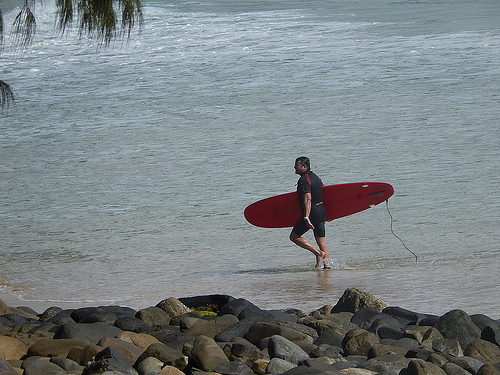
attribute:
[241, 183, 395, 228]
board — red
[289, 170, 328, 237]
wetsuit — black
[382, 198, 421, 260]
cable — black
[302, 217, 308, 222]
watch — white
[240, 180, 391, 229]
board — red, black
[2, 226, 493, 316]
water — shallow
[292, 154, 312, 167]
hair — short, dark, wet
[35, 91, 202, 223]
ocean water — Calm , blue 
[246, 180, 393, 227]
surfboard — dark red, one, red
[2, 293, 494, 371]
rocks — large, dark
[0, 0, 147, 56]
leaves — dripping 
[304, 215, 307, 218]
watch — white 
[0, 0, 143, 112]
tree — green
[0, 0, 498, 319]
water — light grey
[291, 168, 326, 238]
wetsuit — short, black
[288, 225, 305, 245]
knee — bent